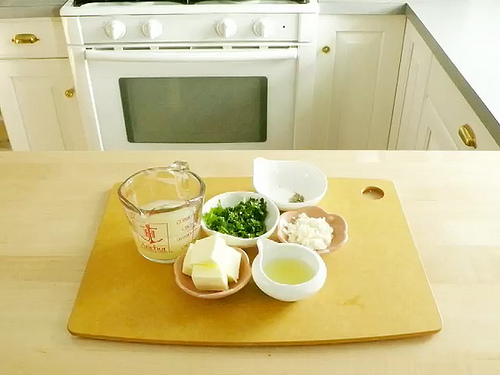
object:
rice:
[284, 214, 333, 246]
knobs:
[215, 19, 238, 38]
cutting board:
[65, 177, 442, 344]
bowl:
[250, 154, 327, 209]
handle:
[81, 45, 300, 62]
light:
[282, 25, 285, 28]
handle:
[13, 36, 41, 45]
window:
[116, 75, 273, 145]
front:
[63, 10, 330, 156]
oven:
[67, 36, 322, 148]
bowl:
[174, 242, 253, 297]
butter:
[182, 235, 241, 281]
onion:
[288, 192, 304, 202]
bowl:
[271, 207, 347, 251]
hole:
[360, 185, 385, 201]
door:
[316, 12, 391, 151]